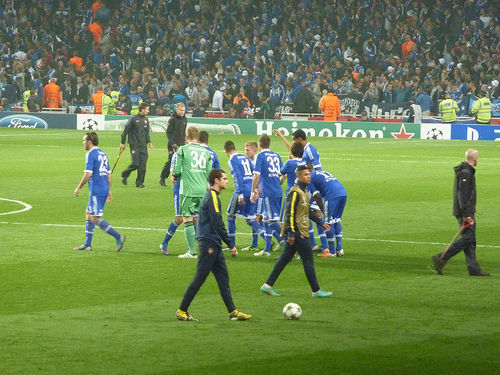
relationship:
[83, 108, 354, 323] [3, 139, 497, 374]
players on field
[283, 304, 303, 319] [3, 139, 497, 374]
ball on field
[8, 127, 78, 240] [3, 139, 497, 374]
turf on field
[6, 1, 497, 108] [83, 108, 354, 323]
spectators watching players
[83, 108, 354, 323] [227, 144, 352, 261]
players in uniforms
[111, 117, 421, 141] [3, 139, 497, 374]
sign behind field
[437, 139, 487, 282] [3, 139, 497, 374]
man on field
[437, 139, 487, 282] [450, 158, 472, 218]
man wears jacket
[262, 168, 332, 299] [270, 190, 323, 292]
man in outfit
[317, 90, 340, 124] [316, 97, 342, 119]
person in suit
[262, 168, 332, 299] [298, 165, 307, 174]
man has hair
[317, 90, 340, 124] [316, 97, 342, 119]
person wears suit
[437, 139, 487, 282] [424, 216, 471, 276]
man carries pitchfork